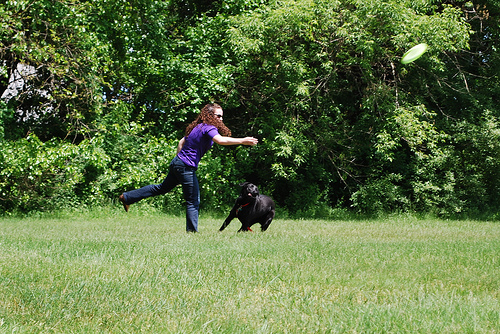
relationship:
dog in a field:
[221, 183, 275, 233] [4, 213, 500, 334]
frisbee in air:
[404, 41, 425, 64] [2, 1, 498, 332]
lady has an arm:
[119, 102, 258, 229] [211, 128, 257, 147]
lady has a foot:
[119, 102, 258, 229] [185, 177, 202, 232]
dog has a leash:
[221, 183, 275, 233] [235, 199, 254, 230]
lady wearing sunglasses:
[119, 102, 258, 229] [213, 113, 223, 119]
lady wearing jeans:
[119, 102, 258, 229] [125, 157, 200, 231]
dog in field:
[221, 183, 275, 233] [4, 213, 500, 334]